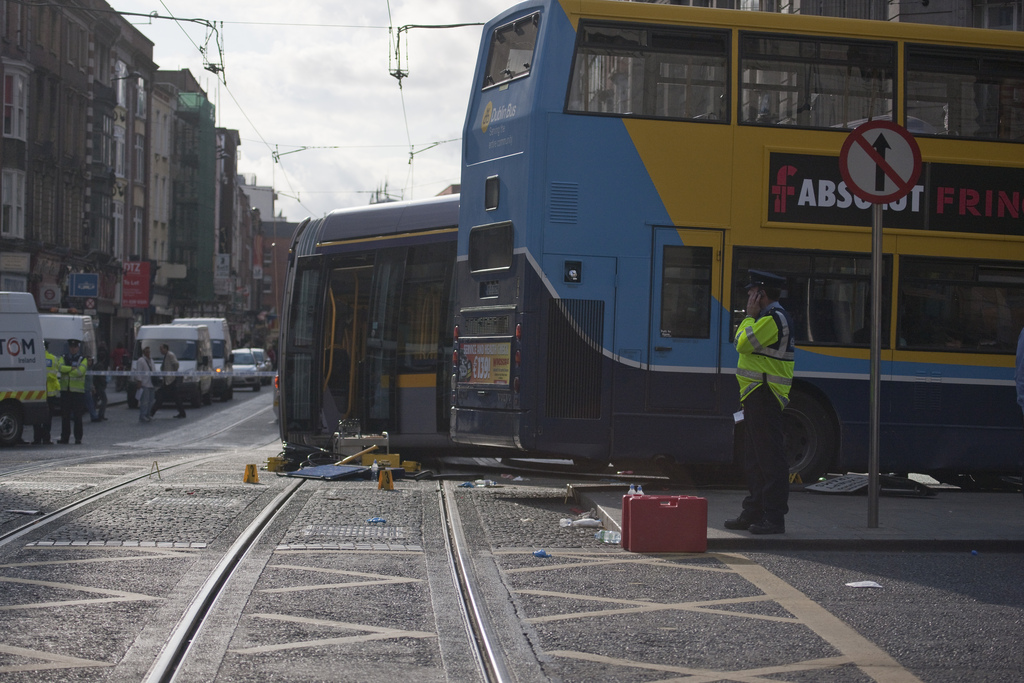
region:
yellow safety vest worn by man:
[723, 253, 804, 405]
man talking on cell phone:
[720, 262, 804, 538]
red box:
[612, 482, 718, 547]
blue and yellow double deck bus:
[479, 17, 983, 496]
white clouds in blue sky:
[299, 68, 344, 103]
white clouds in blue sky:
[321, 172, 370, 199]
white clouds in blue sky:
[384, 131, 427, 164]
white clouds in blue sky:
[255, 68, 300, 113]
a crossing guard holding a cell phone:
[731, 259, 809, 528]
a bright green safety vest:
[731, 316, 795, 397]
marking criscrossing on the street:
[235, 537, 452, 677]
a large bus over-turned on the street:
[252, 179, 455, 484]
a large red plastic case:
[622, 478, 717, 562]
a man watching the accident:
[122, 339, 170, 437]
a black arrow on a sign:
[871, 126, 898, 200]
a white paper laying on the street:
[832, 572, 896, 601]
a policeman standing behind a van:
[59, 328, 101, 446]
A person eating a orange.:
[730, 361, 798, 497]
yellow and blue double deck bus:
[464, 8, 1015, 493]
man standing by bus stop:
[723, 254, 806, 531]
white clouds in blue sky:
[255, 0, 338, 43]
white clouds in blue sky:
[394, 118, 455, 166]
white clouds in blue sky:
[307, 125, 372, 192]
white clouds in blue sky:
[245, 39, 302, 90]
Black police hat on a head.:
[741, 264, 786, 296]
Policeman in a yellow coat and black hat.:
[720, 267, 798, 533]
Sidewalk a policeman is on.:
[572, 474, 1022, 547]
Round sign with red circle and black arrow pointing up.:
[839, 120, 923, 201]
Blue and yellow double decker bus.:
[452, 0, 1022, 491]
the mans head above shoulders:
[731, 255, 792, 310]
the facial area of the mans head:
[743, 276, 757, 309]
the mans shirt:
[718, 303, 807, 403]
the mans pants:
[729, 391, 796, 531]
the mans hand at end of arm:
[729, 285, 767, 317]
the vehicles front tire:
[248, 379, 262, 393]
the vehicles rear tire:
[732, 380, 846, 492]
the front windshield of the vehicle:
[231, 350, 258, 366]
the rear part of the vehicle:
[433, 4, 833, 494]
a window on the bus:
[748, 25, 903, 153]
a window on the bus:
[772, 253, 839, 358]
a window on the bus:
[912, 253, 1011, 378]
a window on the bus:
[687, 241, 704, 319]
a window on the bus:
[588, 25, 681, 127]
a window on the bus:
[512, 1, 555, 100]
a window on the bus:
[330, 291, 373, 352]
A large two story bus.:
[442, 19, 1016, 516]